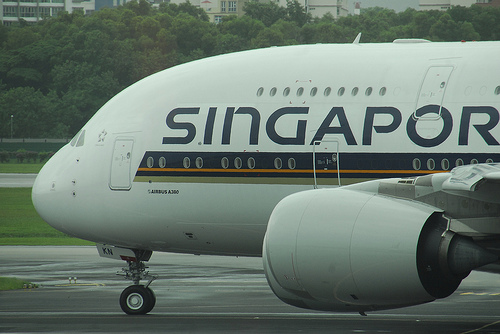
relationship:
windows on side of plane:
[146, 152, 300, 176] [31, 26, 499, 316]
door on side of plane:
[411, 61, 457, 120] [31, 26, 499, 316]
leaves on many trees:
[52, 60, 97, 84] [4, 5, 496, 132]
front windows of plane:
[62, 127, 89, 147] [31, 26, 499, 316]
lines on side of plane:
[130, 163, 446, 183] [31, 26, 499, 316]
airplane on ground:
[29, 28, 499, 313] [5, 248, 499, 332]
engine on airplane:
[254, 167, 491, 317] [29, 28, 499, 313]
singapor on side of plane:
[164, 104, 498, 145] [31, 26, 499, 316]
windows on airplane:
[256, 85, 386, 95] [29, 28, 499, 313]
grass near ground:
[3, 278, 34, 288] [0, 244, 499, 334]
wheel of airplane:
[120, 284, 155, 317] [29, 28, 499, 313]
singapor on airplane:
[164, 104, 498, 145] [29, 28, 499, 313]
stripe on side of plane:
[132, 150, 499, 186] [31, 26, 499, 316]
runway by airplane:
[23, 247, 95, 323] [29, 28, 499, 313]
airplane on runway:
[29, 28, 499, 313] [23, 247, 95, 323]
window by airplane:
[231, 153, 243, 171] [29, 28, 499, 313]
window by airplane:
[246, 156, 258, 170] [29, 28, 499, 313]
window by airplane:
[220, 155, 230, 171] [29, 28, 499, 313]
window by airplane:
[194, 154, 204, 168] [29, 28, 499, 313]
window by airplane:
[181, 155, 191, 170] [29, 28, 499, 313]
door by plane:
[411, 61, 457, 120] [31, 26, 499, 316]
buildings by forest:
[1, 14, 96, 20] [15, 7, 135, 128]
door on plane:
[411, 60, 456, 120] [31, 26, 499, 316]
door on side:
[411, 60, 456, 120] [78, 59, 495, 164]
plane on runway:
[31, 26, 499, 316] [13, 287, 278, 323]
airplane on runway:
[29, 28, 499, 313] [1, 245, 496, 330]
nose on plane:
[2, 108, 143, 241] [31, 26, 499, 316]